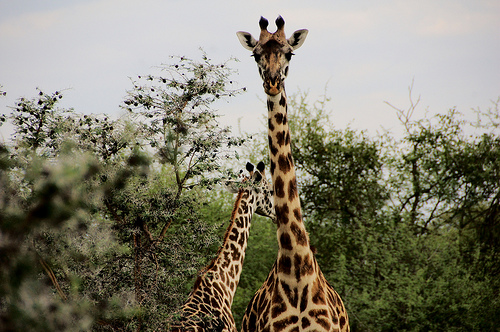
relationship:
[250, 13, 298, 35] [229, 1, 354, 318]
horns on giraffe's head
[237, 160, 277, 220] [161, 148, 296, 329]
head of a giraffe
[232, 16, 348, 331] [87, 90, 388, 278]
giraffe looking at camera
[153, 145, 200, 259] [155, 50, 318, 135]
left giraffe eye looking at camera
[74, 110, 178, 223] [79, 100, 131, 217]
tip of brush high up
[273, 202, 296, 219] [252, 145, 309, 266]
spot on neck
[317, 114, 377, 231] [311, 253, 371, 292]
right giraffe ear for hearing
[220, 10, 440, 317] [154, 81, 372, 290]
giraffe are two in number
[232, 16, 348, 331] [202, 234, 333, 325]
giraffe are two in number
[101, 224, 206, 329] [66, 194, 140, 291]
thorns are white in color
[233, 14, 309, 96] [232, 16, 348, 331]
head of giraffe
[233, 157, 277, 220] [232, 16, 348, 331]
head of giraffe